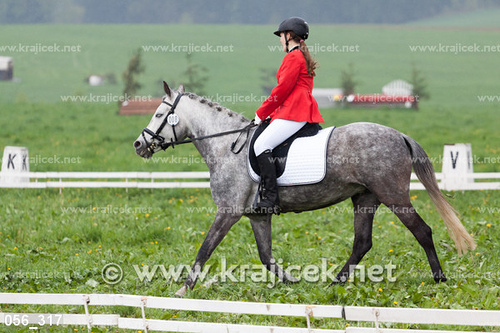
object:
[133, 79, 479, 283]
horse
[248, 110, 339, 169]
pants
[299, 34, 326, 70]
hair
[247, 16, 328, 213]
woman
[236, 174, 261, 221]
boots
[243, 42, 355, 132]
jacket